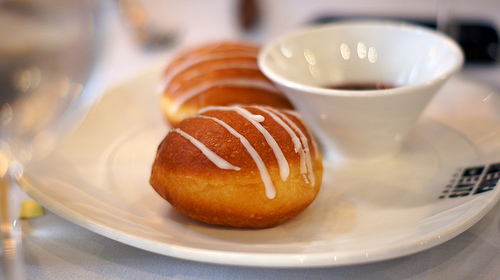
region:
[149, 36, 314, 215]
Delicious looking pastries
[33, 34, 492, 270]
Treats on top of a clean white plate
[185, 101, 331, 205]
White stripes of frosting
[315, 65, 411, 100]
Brown liquid in the cup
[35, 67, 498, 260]
A white plate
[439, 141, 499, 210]
Black writing on the plate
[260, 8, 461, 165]
A small white bowl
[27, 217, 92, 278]
A white table beneath the plate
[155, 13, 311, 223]
Confectionary goods next to the small bowl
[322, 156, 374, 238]
No crumbs on the plate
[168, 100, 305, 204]
pastry on white plate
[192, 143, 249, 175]
white frosting on pastry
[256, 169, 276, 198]
white frosting on pastry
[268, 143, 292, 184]
white frosting on pastry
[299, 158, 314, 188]
white frosting on pastry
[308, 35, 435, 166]
compote on white plate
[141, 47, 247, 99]
pastry on white plate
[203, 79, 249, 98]
white frosting on pastry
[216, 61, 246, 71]
white frosting on pastry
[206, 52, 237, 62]
white frosting on pastry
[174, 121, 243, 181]
White icing on pastry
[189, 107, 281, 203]
White icing on pastry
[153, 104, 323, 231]
Pastry next to small white cup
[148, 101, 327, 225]
Pastry on small round white dish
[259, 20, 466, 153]
White cup on dish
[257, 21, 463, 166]
Small cup on dish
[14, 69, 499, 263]
White plate on white table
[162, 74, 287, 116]
White icing on pastry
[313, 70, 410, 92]
Brown sauce in small white cup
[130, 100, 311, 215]
doughnut with white icing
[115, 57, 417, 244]
dessert on white plate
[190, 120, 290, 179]
white stripes on doughnut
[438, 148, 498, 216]
black logo on white plate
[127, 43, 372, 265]
puffy doughnuts with dipping sauce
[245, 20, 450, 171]
dipping sauce for dessert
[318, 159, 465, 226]
round white ceramic plate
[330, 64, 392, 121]
brown sauce in white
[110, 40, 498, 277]
doughnuts with white frosting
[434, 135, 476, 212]
black letters on white plate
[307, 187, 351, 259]
the plate is white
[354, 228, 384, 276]
the plate is white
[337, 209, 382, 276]
the plate is white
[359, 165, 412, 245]
the plate is white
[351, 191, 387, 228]
the plate is white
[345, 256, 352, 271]
the plate is white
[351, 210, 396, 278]
the plate is white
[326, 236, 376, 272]
the plate is white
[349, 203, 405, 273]
the plate is white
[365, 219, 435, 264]
the plate is white